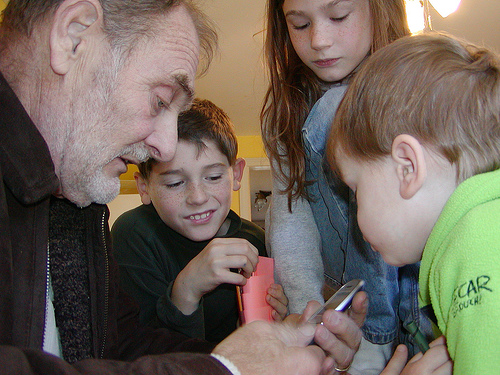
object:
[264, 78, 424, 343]
jacket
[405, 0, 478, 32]
light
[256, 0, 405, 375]
girl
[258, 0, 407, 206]
brown hair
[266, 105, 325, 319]
sweatshirt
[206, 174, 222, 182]
eye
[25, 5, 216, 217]
car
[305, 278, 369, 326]
phone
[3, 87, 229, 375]
coat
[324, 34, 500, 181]
hair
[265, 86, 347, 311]
sweater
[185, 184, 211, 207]
nose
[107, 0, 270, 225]
wall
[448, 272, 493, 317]
lettering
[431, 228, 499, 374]
sleeve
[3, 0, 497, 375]
talking man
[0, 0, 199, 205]
man's head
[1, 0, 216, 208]
head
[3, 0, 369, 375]
man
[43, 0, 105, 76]
ear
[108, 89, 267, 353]
boy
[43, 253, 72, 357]
shirt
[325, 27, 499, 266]
head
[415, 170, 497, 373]
shirt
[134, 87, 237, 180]
hair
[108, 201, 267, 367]
shirt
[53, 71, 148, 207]
beard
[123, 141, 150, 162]
mustache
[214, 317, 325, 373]
hand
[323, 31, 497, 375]
boy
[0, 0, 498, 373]
family